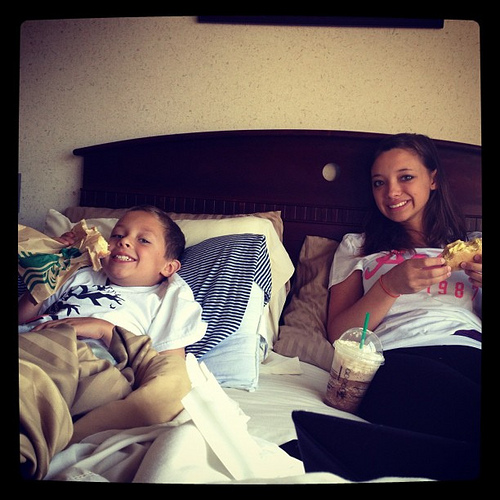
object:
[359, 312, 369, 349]
straw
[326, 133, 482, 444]
woman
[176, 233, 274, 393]
pillow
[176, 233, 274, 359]
pillow case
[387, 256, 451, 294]
hand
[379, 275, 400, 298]
hair tie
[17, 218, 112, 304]
starbucks bag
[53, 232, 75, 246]
boy's hand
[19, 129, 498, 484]
bed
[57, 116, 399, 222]
bed smiling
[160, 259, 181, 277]
ear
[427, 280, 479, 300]
1987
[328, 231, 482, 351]
woman's shirt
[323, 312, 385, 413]
drink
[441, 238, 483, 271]
sandwich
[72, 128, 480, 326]
headboard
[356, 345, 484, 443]
pants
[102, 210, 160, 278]
face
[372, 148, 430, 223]
face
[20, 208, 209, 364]
boy